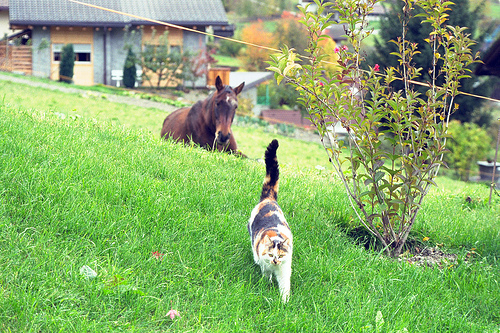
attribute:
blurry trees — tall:
[231, 3, 497, 164]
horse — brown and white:
[159, 71, 243, 158]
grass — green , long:
[8, 149, 251, 327]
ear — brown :
[232, 77, 246, 93]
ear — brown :
[209, 72, 224, 93]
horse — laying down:
[155, 74, 249, 162]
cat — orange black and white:
[248, 150, 303, 303]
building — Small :
[0, 3, 234, 113]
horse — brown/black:
[159, 77, 245, 157]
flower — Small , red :
[153, 249, 162, 262]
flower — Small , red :
[163, 307, 180, 319]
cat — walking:
[239, 133, 303, 298]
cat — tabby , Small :
[246, 135, 305, 305]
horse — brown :
[155, 68, 255, 159]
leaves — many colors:
[298, 36, 358, 117]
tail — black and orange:
[261, 137, 281, 201]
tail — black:
[259, 137, 281, 197]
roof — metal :
[7, 2, 228, 29]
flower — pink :
[369, 60, 380, 74]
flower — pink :
[333, 41, 347, 56]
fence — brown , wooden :
[0, 43, 34, 74]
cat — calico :
[245, 138, 292, 304]